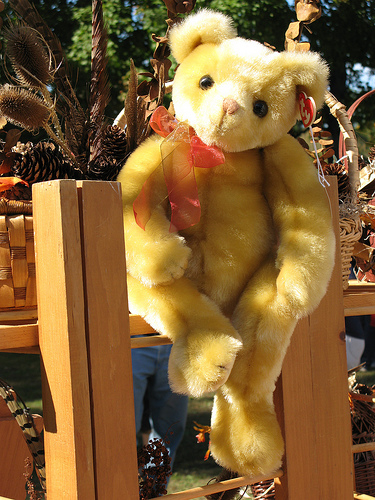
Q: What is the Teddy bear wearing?
A: A red bow.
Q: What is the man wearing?
A: Blue jeans.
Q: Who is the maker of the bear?
A: Ty.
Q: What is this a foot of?
A: A teddy bear.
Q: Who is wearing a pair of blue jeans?
A: A man.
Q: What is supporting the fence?
A: A wooden post.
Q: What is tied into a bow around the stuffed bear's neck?
A: Red ribbon.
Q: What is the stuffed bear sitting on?
A: A wooden ladder.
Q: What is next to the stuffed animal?
A: A basket.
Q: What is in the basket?
A: A dried bouquet.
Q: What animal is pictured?
A: A bear.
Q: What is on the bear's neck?
A: A ribbon.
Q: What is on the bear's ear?
A: A TY tag.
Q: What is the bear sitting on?
A: A wooden object.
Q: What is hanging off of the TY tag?
A: White string.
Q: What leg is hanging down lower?
A: The left leg.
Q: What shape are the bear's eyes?
A: Circular.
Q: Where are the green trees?
A: In the back of the image.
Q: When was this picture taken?
A: Daytime.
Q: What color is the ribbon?
A: Red.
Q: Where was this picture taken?
A: Flea market.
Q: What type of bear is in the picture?
A: Teddy.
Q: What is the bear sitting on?
A: Shelf.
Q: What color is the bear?
A: Tan.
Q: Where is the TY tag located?
A: Bears ears.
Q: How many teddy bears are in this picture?
A: 1.